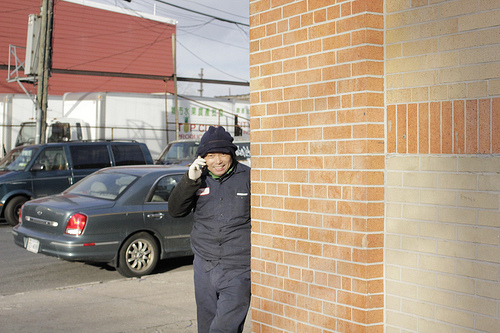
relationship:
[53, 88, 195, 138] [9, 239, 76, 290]
wall boarding road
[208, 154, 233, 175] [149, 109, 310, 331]
face of man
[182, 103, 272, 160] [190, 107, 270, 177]
cap on mans head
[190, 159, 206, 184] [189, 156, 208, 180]
glove on mans hand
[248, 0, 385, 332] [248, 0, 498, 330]
pillar on a building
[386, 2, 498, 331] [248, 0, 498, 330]
wall on building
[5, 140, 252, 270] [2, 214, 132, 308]
vehicles on road